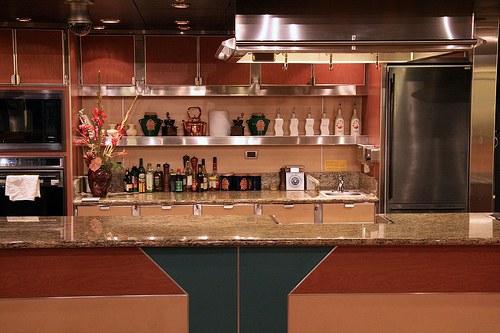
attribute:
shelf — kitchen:
[80, 129, 373, 155]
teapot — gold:
[182, 105, 207, 134]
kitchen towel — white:
[5, 176, 42, 202]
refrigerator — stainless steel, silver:
[380, 58, 470, 214]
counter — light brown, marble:
[74, 170, 380, 204]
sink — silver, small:
[323, 190, 363, 199]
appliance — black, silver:
[0, 90, 69, 217]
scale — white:
[284, 165, 307, 191]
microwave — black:
[0, 89, 66, 152]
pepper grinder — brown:
[161, 161, 172, 193]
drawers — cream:
[75, 201, 376, 224]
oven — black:
[1, 154, 67, 216]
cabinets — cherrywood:
[1, 29, 367, 88]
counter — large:
[0, 213, 499, 331]